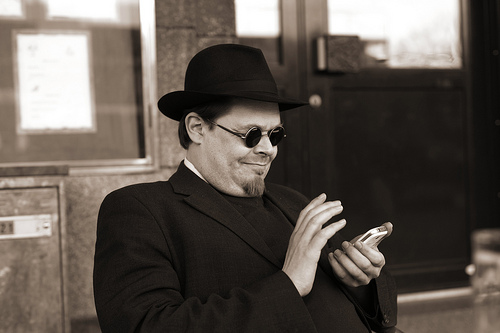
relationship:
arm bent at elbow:
[90, 184, 350, 331] [92, 297, 191, 329]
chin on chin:
[229, 172, 269, 202] [229, 172, 269, 202]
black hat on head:
[155, 40, 310, 120] [177, 100, 287, 198]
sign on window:
[17, 35, 92, 130] [0, 0, 158, 178]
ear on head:
[181, 110, 205, 145] [171, 93, 290, 196]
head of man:
[174, 69, 288, 200] [89, 42, 398, 332]